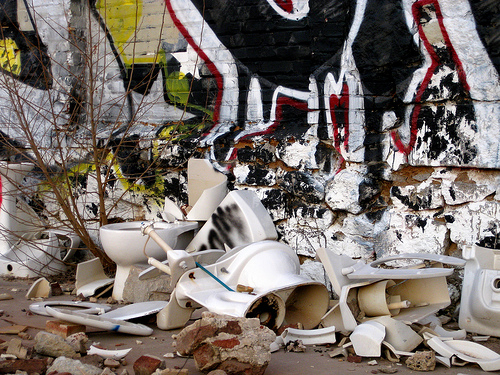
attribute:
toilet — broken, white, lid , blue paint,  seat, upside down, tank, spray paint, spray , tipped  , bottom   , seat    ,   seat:
[125, 198, 414, 338]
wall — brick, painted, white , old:
[130, 7, 497, 199]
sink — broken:
[350, 250, 499, 338]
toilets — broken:
[151, 108, 442, 364]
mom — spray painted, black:
[185, 202, 250, 256]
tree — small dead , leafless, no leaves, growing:
[16, 82, 128, 266]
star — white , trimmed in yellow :
[165, 26, 219, 89]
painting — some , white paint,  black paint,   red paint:
[2, 2, 497, 164]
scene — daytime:
[13, 5, 498, 368]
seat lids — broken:
[1, 159, 499, 371]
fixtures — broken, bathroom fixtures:
[0, 158, 499, 373]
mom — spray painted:
[198, 204, 247, 254]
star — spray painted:
[116, 60, 207, 160]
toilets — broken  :
[57, 165, 458, 335]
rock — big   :
[38, 324, 114, 364]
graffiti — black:
[82, 183, 478, 347]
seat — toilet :
[91, 175, 411, 373]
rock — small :
[38, 326, 88, 366]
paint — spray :
[79, 157, 443, 352]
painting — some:
[14, 9, 476, 174]